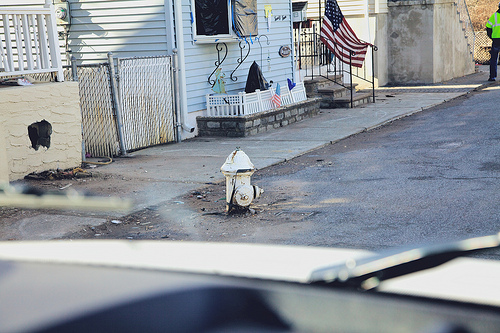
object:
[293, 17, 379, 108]
railing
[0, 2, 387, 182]
building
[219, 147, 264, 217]
hydrant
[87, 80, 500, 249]
road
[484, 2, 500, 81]
man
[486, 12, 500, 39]
vest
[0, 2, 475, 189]
wall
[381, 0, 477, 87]
building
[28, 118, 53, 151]
hole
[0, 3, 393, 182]
wall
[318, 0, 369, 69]
american flag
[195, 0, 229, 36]
plastic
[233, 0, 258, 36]
plastic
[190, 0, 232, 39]
window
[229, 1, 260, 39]
window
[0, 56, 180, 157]
chain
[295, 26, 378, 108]
porch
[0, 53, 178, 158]
porch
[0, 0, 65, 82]
fence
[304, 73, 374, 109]
staircase